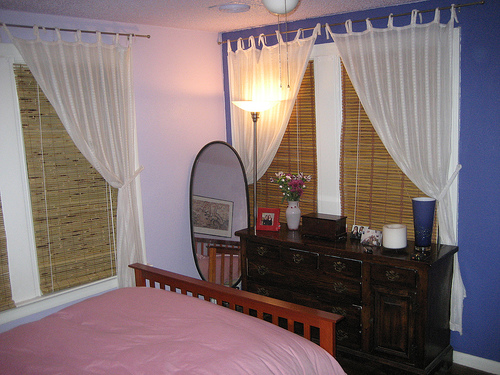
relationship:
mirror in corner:
[160, 120, 296, 282] [149, 28, 324, 324]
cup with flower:
[411, 196, 437, 251] [280, 169, 310, 202]